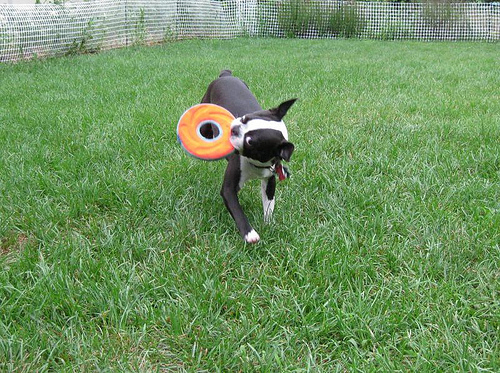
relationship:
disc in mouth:
[176, 103, 238, 161] [222, 108, 245, 163]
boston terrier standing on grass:
[199, 67, 298, 242] [18, 56, 499, 363]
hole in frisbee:
[202, 117, 220, 142] [173, 92, 249, 171]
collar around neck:
[247, 158, 288, 183] [237, 157, 291, 178]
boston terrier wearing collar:
[199, 67, 298, 242] [246, 158, 282, 179]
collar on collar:
[248, 160, 291, 181] [264, 152, 297, 190]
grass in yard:
[2, 32, 497, 371] [353, 129, 449, 265]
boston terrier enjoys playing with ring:
[199, 67, 298, 242] [154, 83, 234, 168]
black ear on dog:
[270, 97, 299, 119] [196, 65, 301, 247]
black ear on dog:
[277, 140, 295, 162] [196, 65, 301, 247]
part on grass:
[340, 245, 402, 307] [2, 32, 497, 371]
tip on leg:
[246, 227, 256, 247] [225, 160, 252, 255]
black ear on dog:
[277, 140, 295, 162] [154, 57, 321, 252]